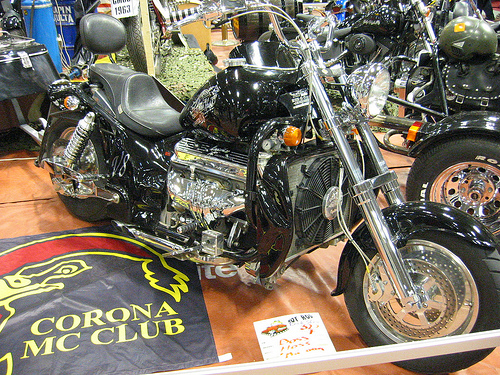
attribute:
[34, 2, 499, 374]
motorcycle — black, large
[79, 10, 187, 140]
seat — leather, grey, black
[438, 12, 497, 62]
helmet — green, army green, dark green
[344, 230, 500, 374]
wheel — black, silver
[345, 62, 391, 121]
headlight — silver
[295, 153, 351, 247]
ventilation — black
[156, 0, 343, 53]
handelbars — silver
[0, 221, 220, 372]
flag — black, red, yellow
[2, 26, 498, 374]
floor — burnt orange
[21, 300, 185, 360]
words — yellow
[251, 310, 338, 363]
paper — white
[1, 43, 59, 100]
bag — leather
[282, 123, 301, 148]
reflector — orange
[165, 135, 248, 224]
silver — shiny